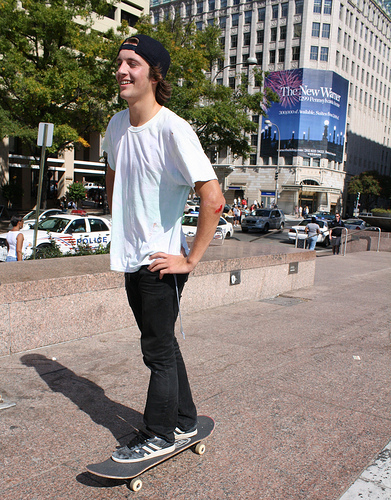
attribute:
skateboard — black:
[85, 411, 214, 491]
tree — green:
[1, 0, 129, 208]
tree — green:
[116, 16, 277, 169]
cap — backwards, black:
[117, 31, 170, 81]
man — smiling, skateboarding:
[100, 35, 226, 464]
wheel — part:
[31, 242, 60, 259]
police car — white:
[1, 208, 112, 260]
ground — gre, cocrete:
[2, 251, 389, 498]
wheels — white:
[127, 441, 204, 491]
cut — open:
[212, 204, 224, 215]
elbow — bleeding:
[201, 194, 227, 218]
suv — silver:
[239, 205, 285, 234]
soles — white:
[111, 426, 201, 464]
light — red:
[69, 207, 85, 215]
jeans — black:
[122, 264, 198, 443]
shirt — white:
[99, 105, 218, 274]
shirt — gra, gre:
[306, 222, 319, 238]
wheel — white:
[128, 477, 143, 493]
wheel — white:
[195, 441, 207, 455]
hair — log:
[148, 63, 174, 106]